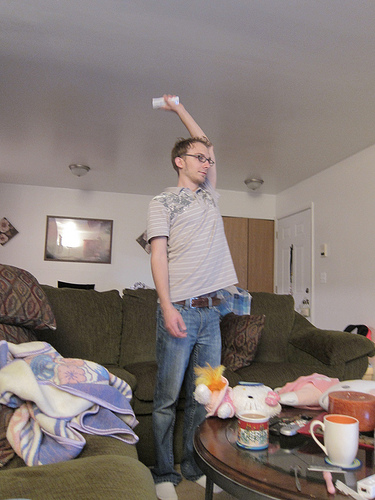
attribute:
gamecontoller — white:
[145, 89, 184, 108]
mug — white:
[305, 417, 365, 468]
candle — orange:
[314, 470, 342, 499]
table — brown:
[192, 426, 280, 499]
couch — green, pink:
[1, 285, 148, 496]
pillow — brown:
[0, 260, 42, 324]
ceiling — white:
[10, 0, 360, 139]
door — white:
[268, 217, 314, 299]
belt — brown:
[182, 295, 225, 309]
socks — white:
[155, 478, 180, 495]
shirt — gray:
[144, 189, 241, 301]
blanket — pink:
[3, 337, 137, 452]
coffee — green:
[225, 411, 272, 454]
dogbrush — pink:
[302, 464, 347, 498]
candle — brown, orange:
[322, 391, 373, 429]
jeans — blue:
[139, 317, 212, 472]